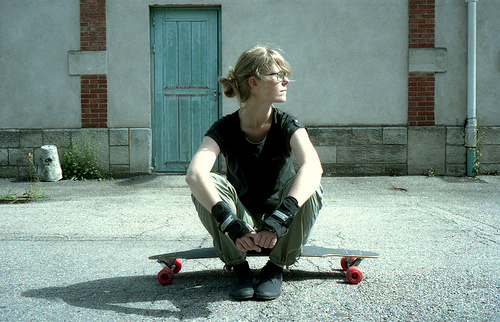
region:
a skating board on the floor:
[306, 245, 378, 277]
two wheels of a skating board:
[339, 258, 359, 283]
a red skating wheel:
[345, 265, 362, 284]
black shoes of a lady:
[233, 257, 283, 302]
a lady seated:
[192, 29, 318, 299]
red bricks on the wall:
[409, 75, 436, 122]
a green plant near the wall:
[71, 139, 107, 181]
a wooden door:
[152, 8, 217, 134]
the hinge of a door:
[153, 42, 157, 55]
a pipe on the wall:
[464, 5, 484, 165]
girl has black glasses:
[238, 67, 290, 78]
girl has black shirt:
[200, 109, 304, 209]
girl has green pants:
[181, 159, 306, 265]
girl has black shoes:
[217, 274, 292, 314]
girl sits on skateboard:
[150, 228, 365, 279]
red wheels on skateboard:
[335, 251, 362, 284]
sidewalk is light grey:
[375, 201, 479, 308]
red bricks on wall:
[418, 1, 455, 110]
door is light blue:
[152, 27, 213, 159]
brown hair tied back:
[214, 64, 231, 103]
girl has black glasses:
[246, 74, 294, 87]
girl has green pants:
[220, 156, 313, 274]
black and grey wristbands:
[208, 194, 308, 251]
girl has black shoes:
[235, 230, 290, 302]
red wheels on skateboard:
[163, 261, 195, 288]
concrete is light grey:
[355, 199, 456, 296]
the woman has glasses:
[176, 47, 330, 306]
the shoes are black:
[223, 260, 285, 302]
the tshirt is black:
[211, 126, 320, 171]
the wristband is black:
[208, 202, 251, 244]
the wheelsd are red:
[331, 252, 368, 284]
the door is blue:
[153, 15, 210, 168]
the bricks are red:
[406, 75, 438, 125]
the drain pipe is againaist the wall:
[461, 11, 482, 171]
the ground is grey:
[398, 269, 477, 315]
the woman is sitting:
[171, 67, 343, 283]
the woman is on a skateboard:
[147, 160, 357, 302]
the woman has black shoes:
[203, 182, 302, 301]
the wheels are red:
[313, 238, 378, 316]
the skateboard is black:
[314, 229, 394, 320]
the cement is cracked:
[30, 218, 110, 315]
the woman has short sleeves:
[187, 110, 231, 257]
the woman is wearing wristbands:
[212, 202, 311, 317]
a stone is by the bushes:
[30, 134, 90, 221]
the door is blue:
[143, 5, 341, 271]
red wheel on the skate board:
[155, 265, 173, 286]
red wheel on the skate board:
[170, 255, 181, 270]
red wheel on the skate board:
[345, 260, 360, 280]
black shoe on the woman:
[220, 257, 250, 298]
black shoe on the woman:
[255, 253, 284, 298]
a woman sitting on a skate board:
[149, 44, 384, 301]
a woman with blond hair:
[184, 43, 323, 299]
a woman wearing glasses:
[183, 45, 331, 303]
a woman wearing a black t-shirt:
[186, 43, 323, 306]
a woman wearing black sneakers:
[182, 44, 324, 300]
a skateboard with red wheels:
[144, 237, 383, 293]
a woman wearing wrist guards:
[182, 45, 327, 301]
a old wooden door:
[145, 3, 225, 178]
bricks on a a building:
[81, 2, 108, 125]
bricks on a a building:
[407, 3, 435, 127]